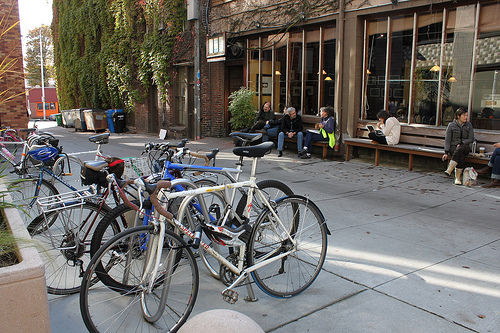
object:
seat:
[233, 140, 274, 158]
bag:
[464, 166, 480, 188]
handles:
[468, 165, 475, 173]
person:
[443, 108, 475, 183]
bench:
[347, 115, 495, 167]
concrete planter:
[0, 175, 51, 331]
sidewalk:
[4, 122, 499, 332]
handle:
[154, 174, 171, 218]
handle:
[108, 172, 127, 208]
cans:
[71, 107, 81, 130]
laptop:
[365, 125, 380, 133]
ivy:
[54, 3, 190, 108]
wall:
[48, 2, 227, 135]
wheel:
[246, 195, 329, 301]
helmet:
[19, 145, 66, 166]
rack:
[38, 187, 99, 213]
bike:
[77, 163, 345, 321]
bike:
[152, 125, 262, 172]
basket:
[120, 157, 152, 183]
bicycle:
[7, 144, 152, 238]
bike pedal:
[222, 289, 240, 304]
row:
[54, 108, 106, 131]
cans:
[85, 108, 109, 131]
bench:
[254, 112, 334, 154]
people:
[252, 100, 279, 143]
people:
[276, 104, 303, 157]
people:
[305, 101, 340, 155]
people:
[366, 108, 403, 147]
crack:
[326, 267, 404, 316]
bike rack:
[138, 227, 174, 323]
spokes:
[103, 245, 136, 289]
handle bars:
[27, 141, 58, 175]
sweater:
[319, 127, 336, 149]